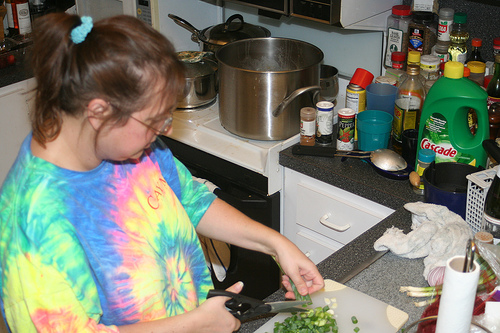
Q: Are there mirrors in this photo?
A: No, there are no mirrors.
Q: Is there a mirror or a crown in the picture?
A: No, there are no mirrors or crowns.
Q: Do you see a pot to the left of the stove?
A: Yes, there are pots to the left of the stove.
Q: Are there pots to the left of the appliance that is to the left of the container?
A: Yes, there are pots to the left of the stove.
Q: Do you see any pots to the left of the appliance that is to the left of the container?
A: Yes, there are pots to the left of the stove.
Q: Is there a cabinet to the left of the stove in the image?
A: No, there are pots to the left of the stove.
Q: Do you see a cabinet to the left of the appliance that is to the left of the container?
A: No, there are pots to the left of the stove.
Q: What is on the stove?
A: The pots are on the stove.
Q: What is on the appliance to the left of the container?
A: The pots are on the stove.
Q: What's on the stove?
A: The pots are on the stove.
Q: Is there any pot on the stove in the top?
A: Yes, there are pots on the stove.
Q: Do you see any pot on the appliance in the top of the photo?
A: Yes, there are pots on the stove.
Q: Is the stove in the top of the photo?
A: Yes, the stove is in the top of the image.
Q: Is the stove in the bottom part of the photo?
A: No, the stove is in the top of the image.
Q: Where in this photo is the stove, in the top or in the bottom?
A: The stove is in the top of the image.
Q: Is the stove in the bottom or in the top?
A: The stove is in the top of the image.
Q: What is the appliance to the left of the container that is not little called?
A: The appliance is a stove.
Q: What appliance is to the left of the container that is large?
A: The appliance is a stove.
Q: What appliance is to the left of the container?
A: The appliance is a stove.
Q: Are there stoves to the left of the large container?
A: Yes, there is a stove to the left of the container.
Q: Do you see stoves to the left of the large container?
A: Yes, there is a stove to the left of the container.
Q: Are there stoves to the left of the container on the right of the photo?
A: Yes, there is a stove to the left of the container.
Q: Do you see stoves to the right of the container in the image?
A: No, the stove is to the left of the container.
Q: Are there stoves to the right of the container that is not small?
A: No, the stove is to the left of the container.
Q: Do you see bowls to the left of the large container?
A: No, there is a stove to the left of the container.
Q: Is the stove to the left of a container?
A: Yes, the stove is to the left of a container.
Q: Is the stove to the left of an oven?
A: No, the stove is to the left of a container.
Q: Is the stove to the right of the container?
A: No, the stove is to the left of the container.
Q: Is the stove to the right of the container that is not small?
A: No, the stove is to the left of the container.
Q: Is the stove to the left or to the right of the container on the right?
A: The stove is to the left of the container.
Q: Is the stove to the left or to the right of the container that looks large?
A: The stove is to the left of the container.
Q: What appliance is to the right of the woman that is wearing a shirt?
A: The appliance is a stove.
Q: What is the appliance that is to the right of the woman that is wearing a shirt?
A: The appliance is a stove.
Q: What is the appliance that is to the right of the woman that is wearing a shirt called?
A: The appliance is a stove.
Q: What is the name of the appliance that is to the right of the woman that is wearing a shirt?
A: The appliance is a stove.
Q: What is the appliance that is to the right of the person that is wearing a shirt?
A: The appliance is a stove.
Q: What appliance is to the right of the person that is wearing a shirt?
A: The appliance is a stove.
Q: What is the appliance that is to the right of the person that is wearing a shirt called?
A: The appliance is a stove.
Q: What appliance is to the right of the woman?
A: The appliance is a stove.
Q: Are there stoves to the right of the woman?
A: Yes, there is a stove to the right of the woman.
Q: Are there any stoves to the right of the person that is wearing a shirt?
A: Yes, there is a stove to the right of the woman.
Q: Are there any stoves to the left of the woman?
A: No, the stove is to the right of the woman.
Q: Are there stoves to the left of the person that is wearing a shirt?
A: No, the stove is to the right of the woman.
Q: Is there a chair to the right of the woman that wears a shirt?
A: No, there is a stove to the right of the woman.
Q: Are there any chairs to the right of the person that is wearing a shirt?
A: No, there is a stove to the right of the woman.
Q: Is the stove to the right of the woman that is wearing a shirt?
A: Yes, the stove is to the right of the woman.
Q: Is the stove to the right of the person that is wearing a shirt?
A: Yes, the stove is to the right of the woman.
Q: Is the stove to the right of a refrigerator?
A: No, the stove is to the right of the woman.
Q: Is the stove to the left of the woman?
A: No, the stove is to the right of the woman.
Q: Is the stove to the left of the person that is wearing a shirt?
A: No, the stove is to the right of the woman.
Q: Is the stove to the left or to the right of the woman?
A: The stove is to the right of the woman.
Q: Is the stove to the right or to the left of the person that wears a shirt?
A: The stove is to the right of the woman.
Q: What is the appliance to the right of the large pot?
A: The appliance is a stove.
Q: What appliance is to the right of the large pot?
A: The appliance is a stove.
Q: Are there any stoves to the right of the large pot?
A: Yes, there is a stove to the right of the pot.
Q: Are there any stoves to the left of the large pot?
A: No, the stove is to the right of the pot.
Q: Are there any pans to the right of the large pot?
A: No, there is a stove to the right of the pot.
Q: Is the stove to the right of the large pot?
A: Yes, the stove is to the right of the pot.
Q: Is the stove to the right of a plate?
A: No, the stove is to the right of the pot.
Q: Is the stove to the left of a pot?
A: No, the stove is to the right of a pot.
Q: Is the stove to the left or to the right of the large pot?
A: The stove is to the right of the pot.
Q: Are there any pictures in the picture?
A: No, there are no pictures.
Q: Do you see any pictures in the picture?
A: No, there are no pictures.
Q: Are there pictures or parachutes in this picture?
A: No, there are no pictures or parachutes.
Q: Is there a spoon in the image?
A: Yes, there is a spoon.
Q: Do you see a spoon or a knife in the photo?
A: Yes, there is a spoon.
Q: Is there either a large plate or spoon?
A: Yes, there is a large spoon.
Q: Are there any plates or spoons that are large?
A: Yes, the spoon is large.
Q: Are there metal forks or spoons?
A: Yes, there is a metal spoon.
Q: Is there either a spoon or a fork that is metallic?
A: Yes, the spoon is metallic.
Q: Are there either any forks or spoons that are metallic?
A: Yes, the spoon is metallic.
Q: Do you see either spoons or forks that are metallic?
A: Yes, the spoon is metallic.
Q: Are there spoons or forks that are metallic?
A: Yes, the spoon is metallic.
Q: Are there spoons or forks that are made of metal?
A: Yes, the spoon is made of metal.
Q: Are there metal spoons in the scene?
A: Yes, there is a metal spoon.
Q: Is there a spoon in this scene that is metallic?
A: Yes, there is a spoon that is metallic.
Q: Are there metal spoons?
A: Yes, there is a spoon that is made of metal.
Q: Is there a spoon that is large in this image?
A: Yes, there is a large spoon.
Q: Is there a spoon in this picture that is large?
A: Yes, there is a spoon that is large.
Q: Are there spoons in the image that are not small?
A: Yes, there is a large spoon.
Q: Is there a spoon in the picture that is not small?
A: Yes, there is a large spoon.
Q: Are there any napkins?
A: No, there are no napkins.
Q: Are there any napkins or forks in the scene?
A: No, there are no napkins or forks.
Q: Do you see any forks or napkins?
A: No, there are no napkins or forks.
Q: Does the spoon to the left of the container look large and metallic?
A: Yes, the spoon is large and metallic.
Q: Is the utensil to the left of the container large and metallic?
A: Yes, the spoon is large and metallic.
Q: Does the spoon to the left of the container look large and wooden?
A: No, the spoon is large but metallic.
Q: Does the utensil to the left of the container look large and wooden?
A: No, the spoon is large but metallic.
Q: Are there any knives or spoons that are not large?
A: No, there is a spoon but it is large.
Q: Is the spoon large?
A: Yes, the spoon is large.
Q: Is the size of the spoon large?
A: Yes, the spoon is large.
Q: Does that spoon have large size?
A: Yes, the spoon is large.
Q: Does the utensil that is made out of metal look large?
A: Yes, the spoon is large.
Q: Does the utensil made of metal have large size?
A: Yes, the spoon is large.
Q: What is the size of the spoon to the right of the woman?
A: The spoon is large.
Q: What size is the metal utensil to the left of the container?
A: The spoon is large.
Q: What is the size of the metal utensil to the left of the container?
A: The spoon is large.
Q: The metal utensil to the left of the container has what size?
A: The spoon is large.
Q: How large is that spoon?
A: The spoon is large.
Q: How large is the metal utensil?
A: The spoon is large.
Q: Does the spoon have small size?
A: No, the spoon is large.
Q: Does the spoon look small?
A: No, the spoon is large.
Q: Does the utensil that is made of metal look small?
A: No, the spoon is large.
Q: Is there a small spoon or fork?
A: No, there is a spoon but it is large.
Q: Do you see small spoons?
A: No, there is a spoon but it is large.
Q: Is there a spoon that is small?
A: No, there is a spoon but it is large.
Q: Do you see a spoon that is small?
A: No, there is a spoon but it is large.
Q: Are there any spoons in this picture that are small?
A: No, there is a spoon but it is large.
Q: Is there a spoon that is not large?
A: No, there is a spoon but it is large.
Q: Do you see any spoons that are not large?
A: No, there is a spoon but it is large.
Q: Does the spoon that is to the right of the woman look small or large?
A: The spoon is large.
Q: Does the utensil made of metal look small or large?
A: The spoon is large.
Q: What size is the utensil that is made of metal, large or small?
A: The spoon is large.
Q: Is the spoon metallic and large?
A: Yes, the spoon is metallic and large.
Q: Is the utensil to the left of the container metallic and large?
A: Yes, the spoon is metallic and large.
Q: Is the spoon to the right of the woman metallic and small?
A: No, the spoon is metallic but large.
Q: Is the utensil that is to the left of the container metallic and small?
A: No, the spoon is metallic but large.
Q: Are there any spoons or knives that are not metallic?
A: No, there is a spoon but it is metallic.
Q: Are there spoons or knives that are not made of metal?
A: No, there is a spoon but it is made of metal.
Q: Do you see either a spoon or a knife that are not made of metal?
A: No, there is a spoon but it is made of metal.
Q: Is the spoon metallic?
A: Yes, the spoon is metallic.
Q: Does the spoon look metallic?
A: Yes, the spoon is metallic.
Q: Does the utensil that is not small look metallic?
A: Yes, the spoon is metallic.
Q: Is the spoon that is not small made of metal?
A: Yes, the spoon is made of metal.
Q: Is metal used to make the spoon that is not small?
A: Yes, the spoon is made of metal.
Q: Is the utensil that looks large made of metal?
A: Yes, the spoon is made of metal.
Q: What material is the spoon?
A: The spoon is made of metal.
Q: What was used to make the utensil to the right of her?
A: The spoon is made of metal.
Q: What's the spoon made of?
A: The spoon is made of metal.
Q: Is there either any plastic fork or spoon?
A: No, there is a spoon but it is metallic.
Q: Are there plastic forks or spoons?
A: No, there is a spoon but it is metallic.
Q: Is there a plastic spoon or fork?
A: No, there is a spoon but it is metallic.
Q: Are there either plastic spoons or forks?
A: No, there is a spoon but it is metallic.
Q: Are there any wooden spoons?
A: No, there is a spoon but it is metallic.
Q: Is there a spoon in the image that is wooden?
A: No, there is a spoon but it is metallic.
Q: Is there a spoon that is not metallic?
A: No, there is a spoon but it is metallic.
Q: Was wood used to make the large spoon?
A: No, the spoon is made of metal.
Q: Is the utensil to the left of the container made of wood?
A: No, the spoon is made of metal.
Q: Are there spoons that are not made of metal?
A: No, there is a spoon but it is made of metal.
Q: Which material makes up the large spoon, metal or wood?
A: The spoon is made of metal.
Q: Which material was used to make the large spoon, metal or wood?
A: The spoon is made of metal.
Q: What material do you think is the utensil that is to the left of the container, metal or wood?
A: The spoon is made of metal.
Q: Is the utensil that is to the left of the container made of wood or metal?
A: The spoon is made of metal.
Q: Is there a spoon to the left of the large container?
A: Yes, there is a spoon to the left of the container.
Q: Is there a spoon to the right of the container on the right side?
A: No, the spoon is to the left of the container.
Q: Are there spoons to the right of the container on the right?
A: No, the spoon is to the left of the container.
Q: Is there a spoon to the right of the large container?
A: No, the spoon is to the left of the container.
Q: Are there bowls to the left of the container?
A: No, there is a spoon to the left of the container.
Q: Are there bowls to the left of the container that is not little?
A: No, there is a spoon to the left of the container.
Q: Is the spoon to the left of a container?
A: Yes, the spoon is to the left of a container.